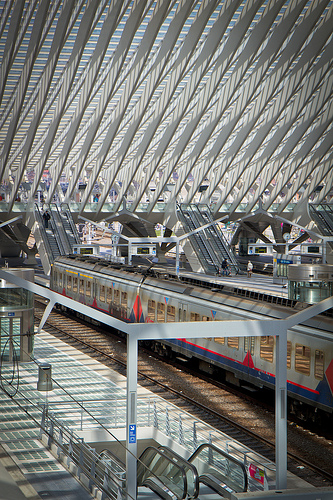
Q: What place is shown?
A: It is a station.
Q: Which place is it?
A: It is a station.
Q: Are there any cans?
A: Yes, there is a can.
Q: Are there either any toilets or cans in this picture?
A: Yes, there is a can.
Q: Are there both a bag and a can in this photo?
A: No, there is a can but no bags.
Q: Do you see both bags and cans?
A: No, there is a can but no bags.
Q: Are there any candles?
A: No, there are no candles.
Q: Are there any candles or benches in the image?
A: No, there are no candles or benches.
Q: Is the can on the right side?
A: No, the can is on the left of the image.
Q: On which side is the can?
A: The can is on the left of the image.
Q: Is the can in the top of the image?
A: No, the can is in the bottom of the image.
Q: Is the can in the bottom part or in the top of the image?
A: The can is in the bottom of the image.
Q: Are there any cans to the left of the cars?
A: Yes, there is a can to the left of the cars.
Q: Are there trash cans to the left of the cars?
A: No, there is a can to the left of the cars.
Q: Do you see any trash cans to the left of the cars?
A: No, there is a can to the left of the cars.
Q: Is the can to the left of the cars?
A: Yes, the can is to the left of the cars.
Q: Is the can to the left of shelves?
A: No, the can is to the left of the cars.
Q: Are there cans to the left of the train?
A: Yes, there is a can to the left of the train.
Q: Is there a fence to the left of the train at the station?
A: No, there is a can to the left of the train.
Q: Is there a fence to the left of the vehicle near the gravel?
A: No, there is a can to the left of the train.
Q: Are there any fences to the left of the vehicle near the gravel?
A: No, there is a can to the left of the train.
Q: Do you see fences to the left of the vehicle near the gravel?
A: No, there is a can to the left of the train.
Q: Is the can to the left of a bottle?
A: No, the can is to the left of the train.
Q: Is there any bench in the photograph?
A: No, there are no benches.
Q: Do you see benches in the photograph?
A: No, there are no benches.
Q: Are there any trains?
A: Yes, there is a train.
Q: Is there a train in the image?
A: Yes, there is a train.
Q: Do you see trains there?
A: Yes, there is a train.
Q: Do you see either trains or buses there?
A: Yes, there is a train.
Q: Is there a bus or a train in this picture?
A: Yes, there is a train.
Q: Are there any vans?
A: No, there are no vans.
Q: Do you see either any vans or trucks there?
A: No, there are no vans or trucks.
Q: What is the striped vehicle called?
A: The vehicle is a train.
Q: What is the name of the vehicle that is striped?
A: The vehicle is a train.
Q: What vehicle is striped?
A: The vehicle is a train.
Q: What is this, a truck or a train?
A: This is a train.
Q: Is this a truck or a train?
A: This is a train.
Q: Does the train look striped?
A: Yes, the train is striped.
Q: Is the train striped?
A: Yes, the train is striped.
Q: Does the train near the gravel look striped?
A: Yes, the train is striped.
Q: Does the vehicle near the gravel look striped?
A: Yes, the train is striped.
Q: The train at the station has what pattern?
A: The train is striped.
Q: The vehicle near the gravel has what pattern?
A: The train is striped.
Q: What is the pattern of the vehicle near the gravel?
A: The train is striped.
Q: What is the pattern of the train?
A: The train is striped.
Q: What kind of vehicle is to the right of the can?
A: The vehicle is a train.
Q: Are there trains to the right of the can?
A: Yes, there is a train to the right of the can.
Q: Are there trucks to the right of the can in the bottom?
A: No, there is a train to the right of the can.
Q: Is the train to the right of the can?
A: Yes, the train is to the right of the can.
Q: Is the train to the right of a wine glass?
A: No, the train is to the right of the can.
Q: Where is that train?
A: The train is at the station.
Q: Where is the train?
A: The train is at the station.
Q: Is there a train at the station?
A: Yes, there is a train at the station.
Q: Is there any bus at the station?
A: No, there is a train at the station.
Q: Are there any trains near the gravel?
A: Yes, there is a train near the gravel.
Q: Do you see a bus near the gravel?
A: No, there is a train near the gravel.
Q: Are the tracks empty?
A: Yes, the tracks are empty.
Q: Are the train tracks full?
A: No, the train tracks are empty.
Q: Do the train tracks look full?
A: No, the train tracks are empty.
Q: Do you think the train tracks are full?
A: No, the train tracks are empty.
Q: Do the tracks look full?
A: No, the tracks are empty.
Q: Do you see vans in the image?
A: No, there are no vans.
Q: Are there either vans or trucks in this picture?
A: No, there are no vans or trucks.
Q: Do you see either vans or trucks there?
A: No, there are no vans or trucks.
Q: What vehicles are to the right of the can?
A: The vehicles are cars.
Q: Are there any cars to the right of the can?
A: Yes, there are cars to the right of the can.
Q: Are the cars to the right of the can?
A: Yes, the cars are to the right of the can.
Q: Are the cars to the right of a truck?
A: No, the cars are to the right of the can.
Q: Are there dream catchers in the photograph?
A: No, there are no dream catchers.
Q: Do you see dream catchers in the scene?
A: No, there are no dream catchers.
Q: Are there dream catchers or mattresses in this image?
A: No, there are no dream catchers or mattresses.